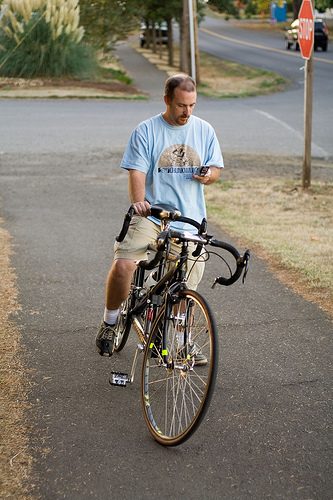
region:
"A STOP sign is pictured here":
[283, 0, 314, 203]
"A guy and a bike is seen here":
[101, 65, 266, 462]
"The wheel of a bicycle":
[122, 286, 227, 459]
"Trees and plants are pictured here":
[0, 0, 211, 92]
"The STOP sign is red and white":
[277, 0, 331, 66]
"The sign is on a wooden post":
[276, 0, 327, 202]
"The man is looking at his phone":
[112, 67, 230, 207]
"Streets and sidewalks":
[0, 6, 331, 497]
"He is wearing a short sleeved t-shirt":
[93, 66, 236, 232]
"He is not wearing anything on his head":
[156, 63, 220, 153]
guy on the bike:
[73, 53, 278, 491]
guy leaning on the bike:
[80, 63, 259, 484]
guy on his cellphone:
[89, 65, 256, 461]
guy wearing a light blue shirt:
[80, 69, 259, 408]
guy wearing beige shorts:
[88, 64, 231, 381]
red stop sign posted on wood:
[275, 0, 329, 200]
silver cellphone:
[191, 163, 222, 189]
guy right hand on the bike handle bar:
[79, 72, 276, 450]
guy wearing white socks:
[82, 67, 258, 460]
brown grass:
[264, 182, 331, 277]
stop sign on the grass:
[292, 1, 322, 191]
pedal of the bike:
[97, 364, 133, 392]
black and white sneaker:
[92, 317, 118, 356]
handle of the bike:
[170, 230, 248, 265]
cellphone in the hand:
[196, 162, 214, 183]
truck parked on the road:
[137, 19, 176, 46]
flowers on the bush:
[6, 3, 91, 75]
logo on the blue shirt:
[146, 135, 203, 178]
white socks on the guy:
[99, 307, 121, 324]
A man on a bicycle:
[85, 67, 255, 449]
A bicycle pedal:
[101, 359, 142, 397]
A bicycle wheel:
[145, 305, 217, 443]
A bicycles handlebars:
[128, 203, 251, 286]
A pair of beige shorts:
[116, 216, 171, 250]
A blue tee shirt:
[123, 114, 221, 206]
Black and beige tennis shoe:
[95, 319, 119, 365]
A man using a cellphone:
[174, 147, 227, 194]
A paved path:
[33, 269, 105, 471]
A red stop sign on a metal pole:
[291, 0, 319, 176]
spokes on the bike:
[160, 377, 189, 412]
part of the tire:
[199, 313, 220, 332]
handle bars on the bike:
[207, 260, 247, 292]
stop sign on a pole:
[291, 2, 316, 198]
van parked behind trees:
[138, 20, 171, 46]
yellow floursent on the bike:
[161, 344, 169, 359]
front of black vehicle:
[278, 14, 298, 56]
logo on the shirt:
[139, 133, 202, 176]